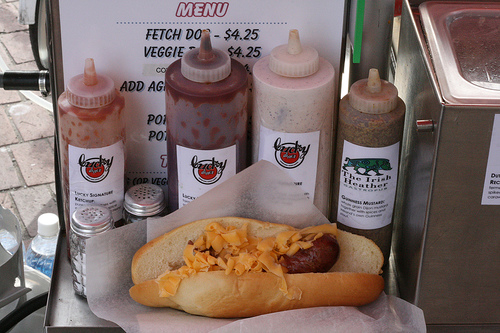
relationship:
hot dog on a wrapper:
[276, 233, 340, 274] [75, 222, 135, 329]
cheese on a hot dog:
[150, 217, 344, 304] [122, 208, 391, 323]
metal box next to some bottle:
[395, 4, 498, 330] [330, 68, 406, 267]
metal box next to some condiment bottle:
[395, 4, 498, 330] [250, 23, 332, 222]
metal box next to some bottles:
[395, 4, 498, 330] [164, 29, 248, 213]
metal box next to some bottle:
[395, 4, 498, 330] [57, 58, 126, 228]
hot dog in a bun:
[276, 233, 340, 274] [122, 213, 387, 320]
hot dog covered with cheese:
[276, 233, 340, 274] [147, 219, 337, 301]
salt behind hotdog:
[67, 205, 116, 299] [137, 211, 384, 296]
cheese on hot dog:
[153, 222, 340, 301] [276, 233, 340, 274]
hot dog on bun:
[179, 230, 340, 275] [122, 213, 387, 320]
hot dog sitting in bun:
[276, 233, 340, 274] [122, 213, 387, 320]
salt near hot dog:
[67, 205, 116, 299] [122, 208, 391, 323]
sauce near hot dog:
[158, 24, 250, 224] [95, 149, 435, 320]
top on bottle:
[36, 212, 58, 238] [25, 212, 62, 279]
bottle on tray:
[58, 62, 137, 256] [28, 188, 409, 330]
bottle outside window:
[347, 55, 411, 230] [9, 5, 87, 315]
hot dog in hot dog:
[276, 233, 340, 274] [122, 208, 391, 323]